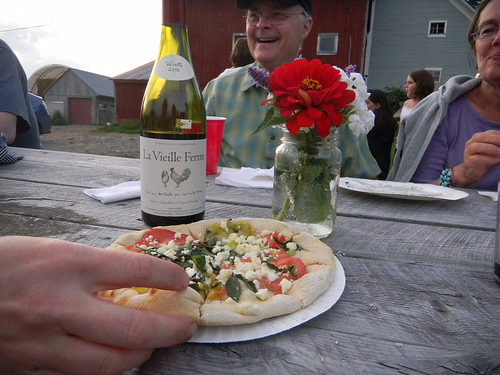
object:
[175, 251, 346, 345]
dish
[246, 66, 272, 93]
flower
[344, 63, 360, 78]
flower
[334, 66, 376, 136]
flower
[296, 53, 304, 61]
flower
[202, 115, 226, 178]
glass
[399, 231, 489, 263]
wood grain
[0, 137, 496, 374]
picnic table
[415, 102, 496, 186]
purple shirt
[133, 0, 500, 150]
buildings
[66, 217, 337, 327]
pizza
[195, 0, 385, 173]
man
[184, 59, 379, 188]
shirt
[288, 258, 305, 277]
tomato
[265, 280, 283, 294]
tomato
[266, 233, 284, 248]
tomato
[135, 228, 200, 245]
tomato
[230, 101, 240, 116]
plaid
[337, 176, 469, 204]
plate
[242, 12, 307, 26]
eyeglasses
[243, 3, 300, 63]
face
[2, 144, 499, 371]
wood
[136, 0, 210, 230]
bottle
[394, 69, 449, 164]
girl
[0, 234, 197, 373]
hand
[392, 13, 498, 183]
woman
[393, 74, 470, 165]
sweater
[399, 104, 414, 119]
tank top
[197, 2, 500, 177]
couple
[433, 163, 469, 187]
woman's wrist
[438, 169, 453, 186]
flower medallion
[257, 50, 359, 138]
daisy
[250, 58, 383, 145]
arrangement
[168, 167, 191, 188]
chickens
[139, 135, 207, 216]
label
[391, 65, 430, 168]
person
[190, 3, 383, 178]
person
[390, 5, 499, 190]
person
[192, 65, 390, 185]
clothes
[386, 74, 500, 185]
clothes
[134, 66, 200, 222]
wine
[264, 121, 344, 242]
jar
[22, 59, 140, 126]
structure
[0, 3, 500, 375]
photo